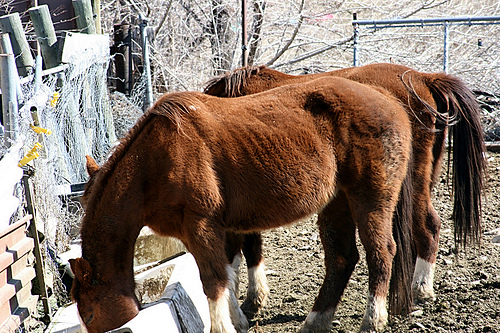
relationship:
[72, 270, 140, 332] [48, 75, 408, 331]
head of a horse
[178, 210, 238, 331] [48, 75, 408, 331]
leg of a horse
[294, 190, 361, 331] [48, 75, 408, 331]
leg of a horse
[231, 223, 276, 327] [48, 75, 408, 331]
leg of a horse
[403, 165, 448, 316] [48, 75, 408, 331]
leg of a horse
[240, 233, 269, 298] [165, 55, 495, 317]
leg of a horse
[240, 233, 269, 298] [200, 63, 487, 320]
leg of a horse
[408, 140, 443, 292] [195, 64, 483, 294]
leg of a horse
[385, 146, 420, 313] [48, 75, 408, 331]
tail of a horse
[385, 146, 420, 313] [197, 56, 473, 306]
tail of a horse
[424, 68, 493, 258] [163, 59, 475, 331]
tail of a horse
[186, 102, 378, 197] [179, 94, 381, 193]
body of a horse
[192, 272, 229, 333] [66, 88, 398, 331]
foot of a horse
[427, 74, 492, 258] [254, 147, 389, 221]
tail of a horse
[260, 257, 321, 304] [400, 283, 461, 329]
rocks on ground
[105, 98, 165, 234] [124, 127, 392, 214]
fur on horse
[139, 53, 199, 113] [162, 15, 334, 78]
branches on tree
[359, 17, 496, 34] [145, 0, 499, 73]
metal fencing near trees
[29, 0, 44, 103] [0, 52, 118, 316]
pipe above fence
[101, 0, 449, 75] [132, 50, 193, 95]
trees are dead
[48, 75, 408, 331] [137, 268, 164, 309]
horse eating food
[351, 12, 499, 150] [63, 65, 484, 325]
metal fencing around horses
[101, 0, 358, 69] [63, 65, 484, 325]
trees behind horses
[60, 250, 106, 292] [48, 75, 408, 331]
ear belonging to horse